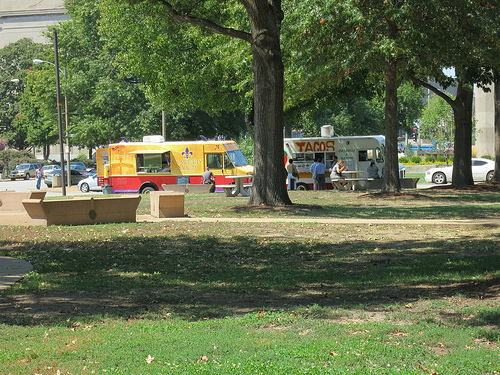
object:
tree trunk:
[165, 0, 293, 205]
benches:
[21, 190, 185, 227]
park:
[75, 46, 279, 228]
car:
[424, 157, 496, 185]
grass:
[0, 186, 500, 340]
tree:
[104, 0, 408, 212]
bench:
[149, 189, 186, 218]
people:
[287, 155, 386, 191]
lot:
[0, 132, 103, 193]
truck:
[96, 135, 255, 194]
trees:
[0, 0, 456, 159]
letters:
[295, 141, 336, 153]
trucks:
[95, 124, 406, 194]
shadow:
[0, 231, 500, 328]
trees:
[1, 1, 500, 210]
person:
[330, 159, 348, 187]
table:
[342, 170, 366, 192]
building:
[0, 0, 76, 50]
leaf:
[145, 354, 155, 364]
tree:
[355, 0, 500, 187]